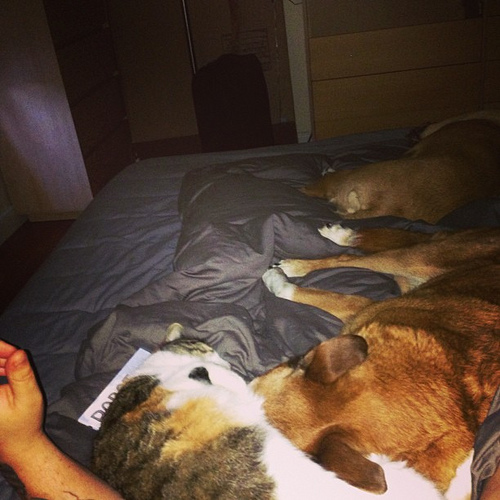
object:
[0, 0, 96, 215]
panels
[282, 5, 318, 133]
wall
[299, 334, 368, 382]
ear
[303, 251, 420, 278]
leg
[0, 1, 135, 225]
shelf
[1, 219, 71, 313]
floor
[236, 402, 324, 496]
belly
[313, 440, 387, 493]
ear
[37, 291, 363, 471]
pillow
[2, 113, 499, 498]
bed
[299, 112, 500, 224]
animal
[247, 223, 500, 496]
animal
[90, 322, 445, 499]
animal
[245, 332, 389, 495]
head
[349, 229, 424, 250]
leg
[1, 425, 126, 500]
arm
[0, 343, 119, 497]
person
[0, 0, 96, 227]
dresser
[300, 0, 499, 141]
tan wood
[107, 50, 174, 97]
wall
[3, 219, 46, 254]
carpet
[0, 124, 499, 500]
comforter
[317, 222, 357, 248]
paw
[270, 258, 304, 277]
paw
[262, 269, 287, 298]
paw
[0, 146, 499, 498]
blanket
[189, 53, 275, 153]
luggage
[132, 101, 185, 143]
wall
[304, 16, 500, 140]
panel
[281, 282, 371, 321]
leg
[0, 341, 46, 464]
hand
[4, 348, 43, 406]
finger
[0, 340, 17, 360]
finger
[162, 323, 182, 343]
ear